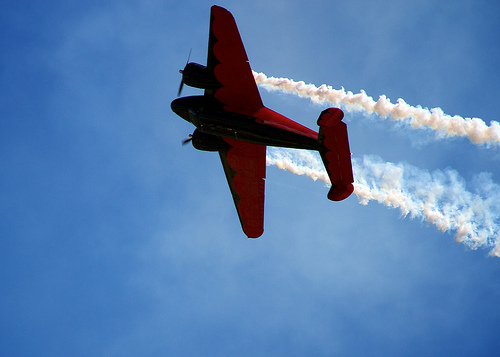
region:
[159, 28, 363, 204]
airplane is red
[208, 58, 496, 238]
airplane leaves white smoke trail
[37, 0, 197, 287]
sky is blue and cloudless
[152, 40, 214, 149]
airplane has two propellers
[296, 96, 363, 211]
airplane has red tail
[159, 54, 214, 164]
two propellers are spinning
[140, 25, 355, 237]
red airplane in sky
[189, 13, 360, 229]
airplane is red and black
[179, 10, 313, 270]
wings have black spots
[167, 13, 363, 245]
airplane is flying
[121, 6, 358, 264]
plane flying in blue sky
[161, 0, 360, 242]
plane facing left in sky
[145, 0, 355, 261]
red plane in the sky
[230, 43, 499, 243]
white smoke coming from plane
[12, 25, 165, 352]
blue sky with light white clouds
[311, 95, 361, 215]
red tail of plane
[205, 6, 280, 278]
red wings with black on side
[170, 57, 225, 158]
two small black engines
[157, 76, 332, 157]
red and black plane blody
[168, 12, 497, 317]
plane leaving trail of white smoke in sky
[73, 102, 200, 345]
the sky is blue and clear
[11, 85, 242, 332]
the sky is blue and clear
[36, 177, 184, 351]
the sky is blue and clear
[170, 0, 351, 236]
the plane is in the sky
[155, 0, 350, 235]
the plane is dark red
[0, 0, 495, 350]
the clear sky is very blue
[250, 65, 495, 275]
plane emits smoke trails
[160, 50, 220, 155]
the plane has two propellers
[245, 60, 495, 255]
smoke trails are white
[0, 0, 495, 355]
the blue sky is clear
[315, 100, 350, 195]
the plane has a tail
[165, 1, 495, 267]
a plane flying through the sky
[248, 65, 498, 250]
the smoke is for skywriting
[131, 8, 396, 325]
red airplane on sky